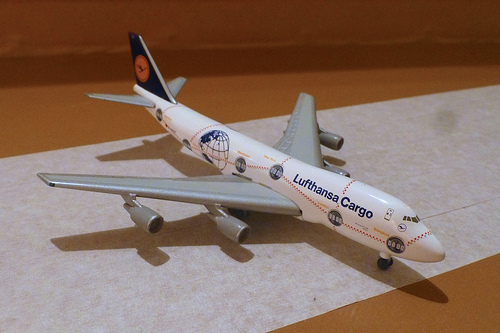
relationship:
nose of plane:
[417, 221, 452, 280] [24, 23, 449, 299]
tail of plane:
[100, 26, 212, 114] [24, 23, 449, 299]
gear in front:
[366, 255, 401, 282] [339, 189, 457, 293]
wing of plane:
[13, 167, 319, 216] [24, 23, 449, 299]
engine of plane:
[98, 198, 265, 246] [24, 23, 449, 299]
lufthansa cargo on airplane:
[290, 174, 376, 221] [24, 23, 449, 299]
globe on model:
[190, 121, 238, 168] [24, 23, 449, 299]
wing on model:
[13, 167, 319, 216] [24, 23, 449, 299]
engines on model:
[98, 198, 265, 246] [24, 23, 449, 299]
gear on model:
[376, 257, 393, 271] [24, 23, 449, 299]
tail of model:
[100, 26, 212, 114] [24, 23, 449, 299]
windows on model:
[400, 203, 424, 235] [24, 23, 449, 299]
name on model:
[290, 174, 376, 221] [24, 23, 449, 299]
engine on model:
[98, 198, 265, 246] [24, 23, 449, 299]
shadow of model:
[16, 226, 430, 332] [24, 23, 449, 299]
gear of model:
[376, 257, 393, 271] [24, 23, 449, 299]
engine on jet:
[98, 198, 265, 246] [24, 23, 449, 299]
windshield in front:
[403, 204, 430, 226] [339, 189, 457, 293]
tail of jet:
[100, 26, 212, 114] [24, 23, 449, 299]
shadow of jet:
[16, 226, 430, 332] [24, 23, 449, 299]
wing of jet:
[13, 167, 319, 216] [24, 23, 449, 299]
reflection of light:
[176, 39, 457, 117] [216, 27, 490, 135]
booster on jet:
[285, 70, 344, 159] [24, 23, 449, 299]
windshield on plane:
[403, 204, 430, 226] [24, 23, 449, 299]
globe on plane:
[198, 130, 230, 171] [24, 23, 449, 299]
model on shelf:
[24, 23, 449, 299] [2, 63, 496, 326]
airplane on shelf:
[36, 22, 447, 276] [2, 63, 496, 326]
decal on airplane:
[378, 207, 407, 222] [24, 23, 449, 299]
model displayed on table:
[24, 23, 449, 299] [14, 21, 444, 310]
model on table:
[24, 23, 449, 299] [14, 21, 444, 310]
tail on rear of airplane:
[100, 26, 212, 114] [36, 31, 446, 270]